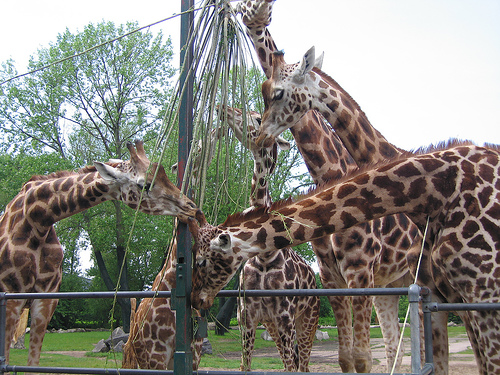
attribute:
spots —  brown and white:
[328, 180, 475, 227]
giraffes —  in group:
[0, 3, 495, 373]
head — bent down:
[247, 44, 322, 169]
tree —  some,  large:
[45, 20, 163, 146]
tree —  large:
[0, 96, 57, 186]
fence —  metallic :
[0, 282, 460, 373]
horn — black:
[263, 46, 287, 71]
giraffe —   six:
[0, 137, 200, 373]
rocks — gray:
[88, 324, 130, 356]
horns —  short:
[121, 137, 149, 165]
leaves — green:
[40, 33, 78, 71]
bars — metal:
[6, 280, 402, 367]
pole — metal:
[400, 286, 429, 373]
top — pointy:
[105, 321, 130, 336]